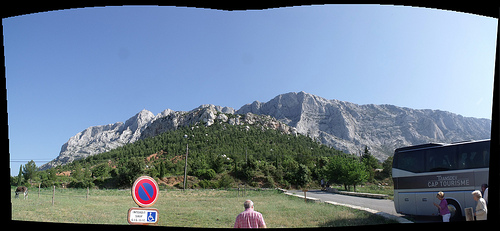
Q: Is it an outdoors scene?
A: Yes, it is outdoors.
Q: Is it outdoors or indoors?
A: It is outdoors.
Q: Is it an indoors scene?
A: No, it is outdoors.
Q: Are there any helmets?
A: No, there are no helmets.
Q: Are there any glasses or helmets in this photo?
A: No, there are no helmets or glasses.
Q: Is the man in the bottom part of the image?
A: Yes, the man is in the bottom of the image.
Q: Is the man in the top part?
A: No, the man is in the bottom of the image.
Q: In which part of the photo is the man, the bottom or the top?
A: The man is in the bottom of the image.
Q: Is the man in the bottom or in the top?
A: The man is in the bottom of the image.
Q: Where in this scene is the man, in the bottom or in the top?
A: The man is in the bottom of the image.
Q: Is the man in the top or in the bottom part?
A: The man is in the bottom of the image.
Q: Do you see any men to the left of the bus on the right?
A: Yes, there is a man to the left of the bus.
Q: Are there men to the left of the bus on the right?
A: Yes, there is a man to the left of the bus.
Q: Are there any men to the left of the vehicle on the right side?
A: Yes, there is a man to the left of the bus.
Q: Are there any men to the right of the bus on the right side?
A: No, the man is to the left of the bus.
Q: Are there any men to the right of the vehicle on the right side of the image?
A: No, the man is to the left of the bus.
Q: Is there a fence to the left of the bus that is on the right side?
A: No, there is a man to the left of the bus.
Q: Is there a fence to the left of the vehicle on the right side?
A: No, there is a man to the left of the bus.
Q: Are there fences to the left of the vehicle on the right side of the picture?
A: No, there is a man to the left of the bus.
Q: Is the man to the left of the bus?
A: Yes, the man is to the left of the bus.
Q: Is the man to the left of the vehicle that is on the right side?
A: Yes, the man is to the left of the bus.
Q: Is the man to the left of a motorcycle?
A: No, the man is to the left of the bus.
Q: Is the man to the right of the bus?
A: No, the man is to the left of the bus.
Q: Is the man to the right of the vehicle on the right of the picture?
A: No, the man is to the left of the bus.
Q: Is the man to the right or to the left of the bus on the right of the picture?
A: The man is to the left of the bus.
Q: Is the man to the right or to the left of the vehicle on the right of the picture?
A: The man is to the left of the bus.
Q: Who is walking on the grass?
A: The man is walking on the grass.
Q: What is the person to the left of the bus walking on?
A: The man is walking on the grass.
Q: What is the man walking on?
A: The man is walking on the grass.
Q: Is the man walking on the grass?
A: Yes, the man is walking on the grass.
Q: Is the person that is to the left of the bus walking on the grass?
A: Yes, the man is walking on the grass.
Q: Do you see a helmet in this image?
A: No, there are no helmets.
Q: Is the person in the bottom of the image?
A: Yes, the person is in the bottom of the image.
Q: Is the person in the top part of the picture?
A: No, the person is in the bottom of the image.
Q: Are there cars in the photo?
A: No, there are no cars.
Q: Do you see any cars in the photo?
A: No, there are no cars.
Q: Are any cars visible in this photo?
A: No, there are no cars.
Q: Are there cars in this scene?
A: No, there are no cars.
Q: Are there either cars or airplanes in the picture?
A: No, there are no cars or airplanes.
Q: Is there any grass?
A: Yes, there is grass.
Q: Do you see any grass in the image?
A: Yes, there is grass.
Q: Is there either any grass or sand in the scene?
A: Yes, there is grass.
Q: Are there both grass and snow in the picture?
A: No, there is grass but no snow.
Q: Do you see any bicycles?
A: No, there are no bicycles.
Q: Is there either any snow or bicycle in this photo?
A: No, there are no bicycles or snow.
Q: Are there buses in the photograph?
A: Yes, there is a bus.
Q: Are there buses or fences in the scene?
A: Yes, there is a bus.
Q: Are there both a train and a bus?
A: No, there is a bus but no trains.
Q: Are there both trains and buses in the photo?
A: No, there is a bus but no trains.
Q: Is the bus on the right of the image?
A: Yes, the bus is on the right of the image.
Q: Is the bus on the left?
A: No, the bus is on the right of the image.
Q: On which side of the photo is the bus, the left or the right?
A: The bus is on the right of the image.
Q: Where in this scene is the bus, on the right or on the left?
A: The bus is on the right of the image.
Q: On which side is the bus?
A: The bus is on the right of the image.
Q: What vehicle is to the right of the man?
A: The vehicle is a bus.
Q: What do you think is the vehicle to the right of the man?
A: The vehicle is a bus.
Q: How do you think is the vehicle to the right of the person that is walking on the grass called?
A: The vehicle is a bus.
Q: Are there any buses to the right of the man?
A: Yes, there is a bus to the right of the man.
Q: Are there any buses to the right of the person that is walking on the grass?
A: Yes, there is a bus to the right of the man.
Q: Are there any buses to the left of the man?
A: No, the bus is to the right of the man.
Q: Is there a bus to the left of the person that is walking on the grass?
A: No, the bus is to the right of the man.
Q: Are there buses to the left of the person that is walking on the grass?
A: No, the bus is to the right of the man.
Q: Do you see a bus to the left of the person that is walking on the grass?
A: No, the bus is to the right of the man.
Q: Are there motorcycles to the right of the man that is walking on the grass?
A: No, there is a bus to the right of the man.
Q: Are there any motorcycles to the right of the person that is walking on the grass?
A: No, there is a bus to the right of the man.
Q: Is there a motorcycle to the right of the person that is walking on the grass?
A: No, there is a bus to the right of the man.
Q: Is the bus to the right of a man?
A: Yes, the bus is to the right of a man.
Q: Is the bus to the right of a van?
A: No, the bus is to the right of a man.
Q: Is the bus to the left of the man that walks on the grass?
A: No, the bus is to the right of the man.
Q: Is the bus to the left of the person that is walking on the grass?
A: No, the bus is to the right of the man.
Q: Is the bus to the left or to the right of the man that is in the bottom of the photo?
A: The bus is to the right of the man.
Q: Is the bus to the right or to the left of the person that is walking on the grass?
A: The bus is to the right of the man.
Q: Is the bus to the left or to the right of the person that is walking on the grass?
A: The bus is to the right of the man.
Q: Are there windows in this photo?
A: Yes, there is a window.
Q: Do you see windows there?
A: Yes, there is a window.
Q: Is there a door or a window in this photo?
A: Yes, there is a window.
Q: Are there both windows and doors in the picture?
A: No, there is a window but no doors.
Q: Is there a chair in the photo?
A: No, there are no chairs.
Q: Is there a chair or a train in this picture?
A: No, there are no chairs or trains.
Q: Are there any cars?
A: No, there are no cars.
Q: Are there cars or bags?
A: No, there are no cars or bags.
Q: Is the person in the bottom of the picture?
A: Yes, the person is in the bottom of the image.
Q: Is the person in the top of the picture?
A: No, the person is in the bottom of the image.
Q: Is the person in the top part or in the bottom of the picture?
A: The person is in the bottom of the image.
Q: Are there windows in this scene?
A: Yes, there is a window.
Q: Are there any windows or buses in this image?
A: Yes, there is a window.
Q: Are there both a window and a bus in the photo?
A: Yes, there are both a window and a bus.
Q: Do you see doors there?
A: No, there are no doors.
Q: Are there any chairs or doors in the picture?
A: No, there are no doors or chairs.